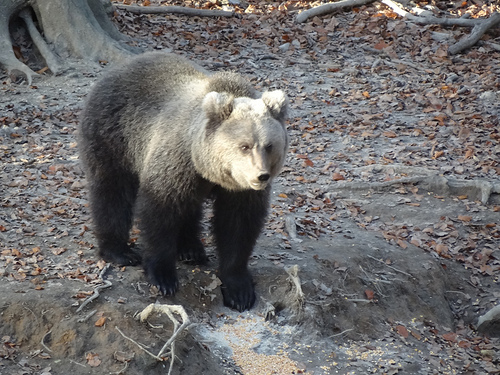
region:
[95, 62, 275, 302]
this is a bear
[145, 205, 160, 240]
the fur is black in color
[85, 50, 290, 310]
the bear is standing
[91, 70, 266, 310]
the bear is big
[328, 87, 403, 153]
this is the ground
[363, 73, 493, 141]
the ground is dirty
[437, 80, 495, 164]
these are some dry leaves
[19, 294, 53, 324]
the ground is sandy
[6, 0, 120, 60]
this is a tree root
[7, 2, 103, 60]
the root is big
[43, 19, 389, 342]
a bear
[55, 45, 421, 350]
a brown bear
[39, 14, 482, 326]
a bear walking in the woods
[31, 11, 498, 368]
brown leaves are on the ground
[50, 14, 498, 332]
a shaft of sun falls on the bear's face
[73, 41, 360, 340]
the bear is standing still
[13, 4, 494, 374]
the ground is littered with leaves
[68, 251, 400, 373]
roots stick up out of the ground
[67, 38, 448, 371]
the bear is looking strait ahead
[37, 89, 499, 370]
the ground slopes down in front of the bear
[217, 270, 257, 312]
Front left paw of a black bear.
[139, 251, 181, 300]
Front right paw of a black bear.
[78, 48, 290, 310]
Black bear with sun shining on its head.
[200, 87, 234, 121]
Right ear of a black bear.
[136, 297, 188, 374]
Tree branch sticking out of the ground.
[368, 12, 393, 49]
Leaves piled up on the ground.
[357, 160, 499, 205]
Large roots sticking out of the ground.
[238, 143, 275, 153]
Dark colored eyes of a black bear.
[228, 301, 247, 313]
Claws on the left paw of a black bear.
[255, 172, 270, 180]
Black end of a black bears nose.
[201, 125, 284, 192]
bear has a grey face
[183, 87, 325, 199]
bear has a grey face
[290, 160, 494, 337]
leaves scattered across ground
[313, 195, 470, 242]
leaves scattered across ground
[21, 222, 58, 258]
leaves scattered across ground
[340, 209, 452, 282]
leaves scattered across ground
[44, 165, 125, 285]
leaves scattered across ground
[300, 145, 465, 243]
leaves scattered across ground